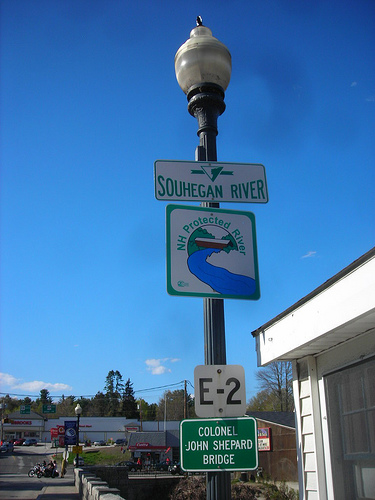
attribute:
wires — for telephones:
[1, 389, 182, 402]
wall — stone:
[69, 463, 104, 492]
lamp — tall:
[174, 14, 240, 115]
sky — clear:
[0, 1, 372, 410]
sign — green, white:
[179, 418, 257, 471]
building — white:
[254, 323, 371, 491]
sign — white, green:
[143, 146, 278, 207]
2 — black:
[225, 376, 241, 402]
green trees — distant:
[10, 372, 151, 414]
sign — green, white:
[178, 412, 262, 470]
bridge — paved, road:
[95, 467, 226, 499]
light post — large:
[170, 12, 236, 498]